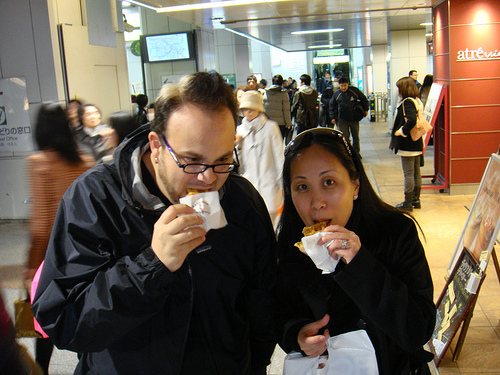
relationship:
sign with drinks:
[434, 165, 498, 326] [454, 190, 498, 279]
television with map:
[134, 1, 226, 66] [151, 41, 187, 59]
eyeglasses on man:
[151, 132, 251, 180] [97, 58, 266, 297]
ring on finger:
[338, 235, 354, 249] [323, 237, 361, 258]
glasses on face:
[151, 132, 251, 180] [146, 112, 264, 198]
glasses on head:
[151, 132, 251, 180] [147, 89, 250, 221]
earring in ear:
[344, 151, 367, 204] [351, 172, 366, 192]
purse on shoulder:
[401, 108, 436, 157] [391, 98, 416, 120]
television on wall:
[134, 1, 226, 66] [124, 10, 202, 79]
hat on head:
[232, 83, 273, 113] [235, 105, 263, 124]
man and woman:
[97, 58, 266, 297] [276, 112, 432, 329]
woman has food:
[276, 112, 432, 329] [282, 220, 348, 248]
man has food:
[97, 58, 266, 297] [282, 220, 348, 248]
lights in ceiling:
[271, 19, 350, 59] [242, 11, 370, 62]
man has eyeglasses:
[97, 58, 266, 297] [151, 132, 251, 180]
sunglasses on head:
[277, 125, 351, 149] [147, 89, 250, 221]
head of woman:
[147, 89, 250, 221] [276, 112, 432, 329]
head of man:
[147, 89, 250, 221] [97, 58, 266, 297]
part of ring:
[335, 231, 349, 248] [338, 235, 354, 249]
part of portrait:
[1, 80, 27, 147] [0, 72, 36, 193]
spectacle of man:
[65, 93, 82, 125] [63, 101, 81, 121]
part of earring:
[345, 194, 357, 202] [344, 151, 367, 204]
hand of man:
[142, 203, 213, 270] [97, 58, 266, 297]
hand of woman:
[142, 203, 213, 270] [276, 112, 432, 329]